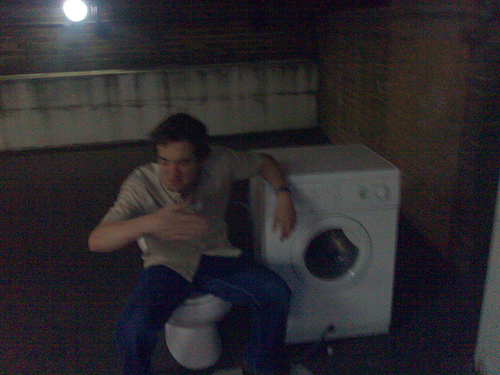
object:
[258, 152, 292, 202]
forearm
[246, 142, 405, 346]
appliance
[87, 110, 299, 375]
man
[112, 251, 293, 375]
jeans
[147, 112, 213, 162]
hair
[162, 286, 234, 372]
toilet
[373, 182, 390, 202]
knob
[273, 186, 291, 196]
watch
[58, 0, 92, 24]
light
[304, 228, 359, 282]
window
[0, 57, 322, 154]
wall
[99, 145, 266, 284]
shirt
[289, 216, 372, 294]
door